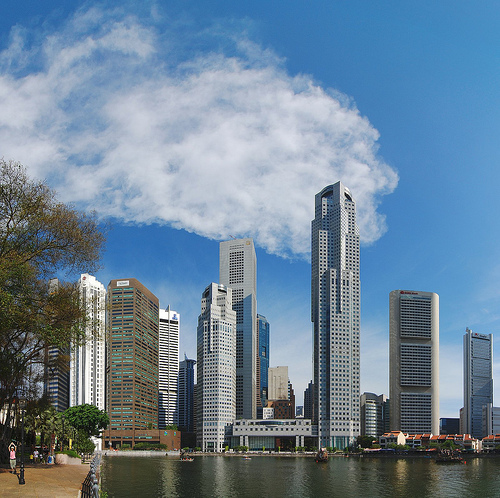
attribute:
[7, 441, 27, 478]
person — stretching, walking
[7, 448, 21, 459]
shirt — pink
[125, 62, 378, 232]
cloud — large, white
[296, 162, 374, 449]
building — high, large, gray, tall, brown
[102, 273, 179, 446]
high rise — brown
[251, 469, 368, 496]
water — dark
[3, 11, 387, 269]
clouds — white, large, puffy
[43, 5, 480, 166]
sky — blue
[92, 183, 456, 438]
skyscrapers — towering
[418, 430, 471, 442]
roofs — red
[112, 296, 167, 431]
panels — vertical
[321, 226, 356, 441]
sides — smooth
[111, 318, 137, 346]
windows — green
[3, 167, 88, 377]
tree — large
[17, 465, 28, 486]
pole — black